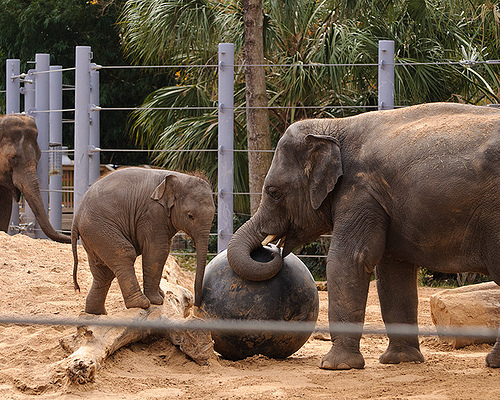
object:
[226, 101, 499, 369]
elephant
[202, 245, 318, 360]
ball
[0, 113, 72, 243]
elephant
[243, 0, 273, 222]
trunk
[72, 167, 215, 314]
elephant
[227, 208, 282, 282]
trunk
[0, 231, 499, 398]
dirt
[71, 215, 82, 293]
tail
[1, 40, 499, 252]
fence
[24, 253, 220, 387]
log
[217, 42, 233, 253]
post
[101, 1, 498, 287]
palm trees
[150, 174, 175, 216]
ear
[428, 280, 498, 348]
rock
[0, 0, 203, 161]
trees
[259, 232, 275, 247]
tusk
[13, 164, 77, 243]
trunk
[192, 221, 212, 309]
trunk